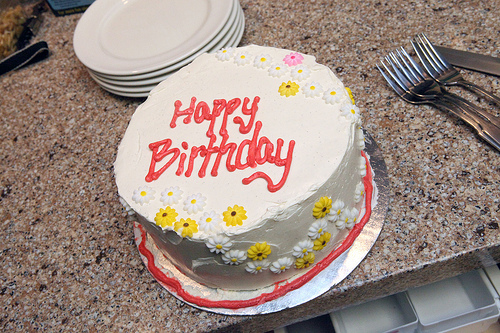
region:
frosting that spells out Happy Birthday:
[153, 96, 294, 165]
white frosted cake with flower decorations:
[154, 93, 340, 268]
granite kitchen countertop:
[5, 78, 82, 322]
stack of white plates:
[86, 5, 237, 40]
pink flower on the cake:
[285, 51, 300, 65]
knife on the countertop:
[443, 46, 495, 62]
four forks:
[381, 47, 441, 99]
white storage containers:
[351, 305, 491, 326]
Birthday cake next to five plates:
[102, 13, 364, 248]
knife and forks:
[381, 33, 496, 129]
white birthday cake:
[91, 36, 384, 316]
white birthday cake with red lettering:
[91, 37, 388, 324]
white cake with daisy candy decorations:
[113, 26, 394, 316]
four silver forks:
[368, 20, 497, 157]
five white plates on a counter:
[36, 2, 252, 105]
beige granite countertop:
[2, 186, 127, 327]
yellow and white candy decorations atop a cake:
[231, 65, 331, 98]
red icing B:
[141, 136, 179, 185]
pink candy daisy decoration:
[276, 48, 305, 66]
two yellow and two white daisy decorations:
[146, 184, 218, 243]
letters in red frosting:
[134, 93, 307, 186]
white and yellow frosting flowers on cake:
[154, 204, 254, 244]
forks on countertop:
[368, 29, 498, 151]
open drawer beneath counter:
[323, 289, 468, 330]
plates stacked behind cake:
[59, 14, 271, 61]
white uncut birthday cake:
[106, 86, 433, 303]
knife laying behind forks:
[410, 33, 498, 75]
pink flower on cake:
[273, 48, 301, 65]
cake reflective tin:
[285, 266, 350, 299]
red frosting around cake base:
[92, 127, 407, 313]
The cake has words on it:
[87, 33, 372, 300]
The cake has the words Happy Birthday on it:
[137, 72, 298, 234]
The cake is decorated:
[109, 33, 381, 308]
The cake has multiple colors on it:
[103, 43, 403, 295]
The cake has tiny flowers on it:
[89, 33, 391, 298]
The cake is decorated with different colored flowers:
[116, 40, 358, 275]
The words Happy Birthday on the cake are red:
[123, 34, 377, 307]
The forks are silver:
[349, 21, 498, 198]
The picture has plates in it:
[22, 3, 254, 275]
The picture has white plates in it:
[51, 0, 264, 125]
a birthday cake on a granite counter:
[75, 42, 416, 322]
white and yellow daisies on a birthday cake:
[151, 195, 301, 276]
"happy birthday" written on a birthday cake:
[145, 90, 290, 190]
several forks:
[377, 30, 497, 152]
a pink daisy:
[282, 50, 302, 65]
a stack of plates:
[82, 0, 237, 80]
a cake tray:
[325, 240, 377, 290]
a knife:
[440, 45, 495, 75]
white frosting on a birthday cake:
[285, 107, 335, 142]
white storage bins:
[344, 282, 495, 329]